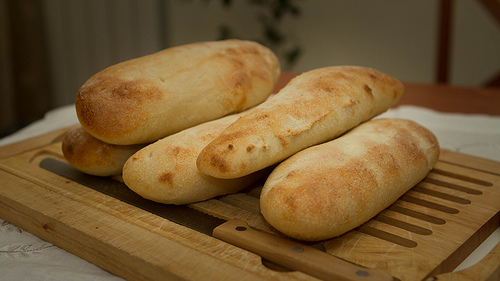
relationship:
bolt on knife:
[236, 224, 246, 231] [40, 156, 393, 280]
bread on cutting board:
[74, 37, 282, 145] [0, 121, 500, 280]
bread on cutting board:
[122, 98, 285, 206] [0, 121, 500, 280]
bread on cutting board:
[62, 124, 150, 177] [0, 121, 500, 280]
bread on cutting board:
[195, 63, 405, 179] [0, 121, 500, 280]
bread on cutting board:
[259, 114, 441, 242] [0, 121, 500, 280]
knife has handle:
[40, 156, 393, 280] [212, 216, 394, 280]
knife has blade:
[40, 156, 393, 280] [39, 156, 227, 237]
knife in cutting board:
[40, 156, 393, 280] [0, 121, 500, 280]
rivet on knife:
[356, 267, 371, 279] [40, 156, 393, 280]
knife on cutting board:
[40, 156, 393, 280] [0, 121, 500, 280]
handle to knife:
[212, 216, 394, 280] [40, 156, 393, 280]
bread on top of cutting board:
[62, 124, 150, 177] [0, 121, 500, 280]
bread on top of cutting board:
[74, 37, 282, 145] [0, 121, 500, 280]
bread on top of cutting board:
[122, 98, 285, 206] [0, 121, 500, 280]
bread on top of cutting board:
[195, 63, 405, 179] [0, 121, 500, 280]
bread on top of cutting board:
[259, 114, 441, 242] [0, 121, 500, 280]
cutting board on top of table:
[0, 121, 500, 280] [256, 68, 499, 116]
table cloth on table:
[1, 99, 499, 280] [256, 68, 499, 116]